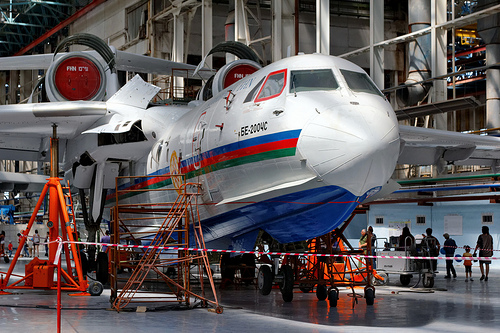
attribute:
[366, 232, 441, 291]
cart — gray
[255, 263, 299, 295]
tires — off ground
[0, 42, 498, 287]
plane — green, red, blue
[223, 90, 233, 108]
bars — handle, small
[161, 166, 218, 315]
pole — orange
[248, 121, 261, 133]
numbers — black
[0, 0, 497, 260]
plane — white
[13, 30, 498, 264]
plane — on display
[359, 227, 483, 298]
people — walking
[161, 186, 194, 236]
lift — brown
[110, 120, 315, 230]
stripe — blue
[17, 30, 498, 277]
airplane — white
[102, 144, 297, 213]
stripe — green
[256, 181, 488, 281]
people — standing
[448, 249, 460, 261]
balloon — blue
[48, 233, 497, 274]
rope — red, white, striped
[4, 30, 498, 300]
airplane — white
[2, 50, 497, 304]
plane — white, roped off, portable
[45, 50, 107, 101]
engine — red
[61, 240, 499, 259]
cross line — red and white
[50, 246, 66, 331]
pole — red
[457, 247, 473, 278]
child — standing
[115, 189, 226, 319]
case — stair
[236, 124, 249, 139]
letters — black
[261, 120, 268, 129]
letter — black